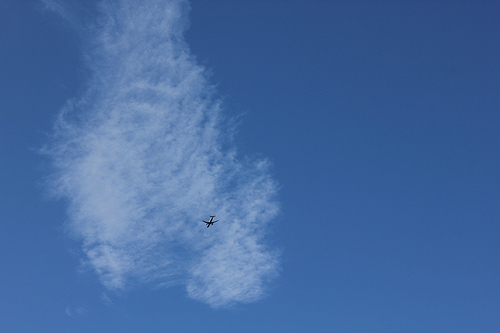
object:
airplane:
[199, 214, 223, 230]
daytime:
[0, 2, 498, 329]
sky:
[0, 0, 496, 332]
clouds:
[44, 1, 286, 310]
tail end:
[209, 213, 216, 218]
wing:
[201, 217, 208, 226]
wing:
[213, 217, 219, 225]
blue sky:
[1, 1, 498, 331]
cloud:
[56, 297, 85, 318]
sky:
[72, 50, 363, 301]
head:
[205, 225, 210, 229]